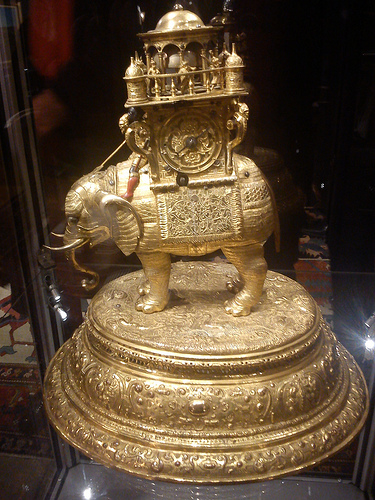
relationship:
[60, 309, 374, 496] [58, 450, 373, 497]
table has surface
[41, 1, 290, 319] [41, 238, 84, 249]
elephant has tusk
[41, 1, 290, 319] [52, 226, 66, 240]
elephant has tusk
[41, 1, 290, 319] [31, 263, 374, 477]
elephant on statue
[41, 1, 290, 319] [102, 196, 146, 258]
elephant has ear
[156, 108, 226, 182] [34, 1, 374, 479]
clock on statue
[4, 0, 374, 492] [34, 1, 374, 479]
case for statue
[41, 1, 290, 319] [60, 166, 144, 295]
elephant has head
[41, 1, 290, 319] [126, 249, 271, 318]
elephant has feet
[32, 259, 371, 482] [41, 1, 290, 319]
base under elephant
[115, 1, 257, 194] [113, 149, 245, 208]
decoration on back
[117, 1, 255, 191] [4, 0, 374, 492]
decoration in case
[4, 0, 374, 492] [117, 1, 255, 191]
case near decoration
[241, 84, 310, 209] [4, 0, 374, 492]
reflection off of case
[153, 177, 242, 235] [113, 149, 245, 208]
blanket over back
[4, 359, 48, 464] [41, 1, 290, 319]
rug behind elephant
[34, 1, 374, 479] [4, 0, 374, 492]
idol in case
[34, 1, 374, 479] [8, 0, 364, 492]
statue in museum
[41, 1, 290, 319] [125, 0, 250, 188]
elephant carrying box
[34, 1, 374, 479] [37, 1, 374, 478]
statue made of gold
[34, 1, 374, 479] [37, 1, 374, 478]
idol made of gold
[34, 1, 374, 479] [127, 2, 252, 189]
statue of building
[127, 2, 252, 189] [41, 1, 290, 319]
building on elephant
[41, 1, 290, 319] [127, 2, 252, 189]
elephant with building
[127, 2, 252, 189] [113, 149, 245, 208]
building on back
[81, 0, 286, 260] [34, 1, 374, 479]
details on statue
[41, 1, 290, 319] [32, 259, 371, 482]
elephant on pedestal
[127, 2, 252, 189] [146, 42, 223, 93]
building with windows